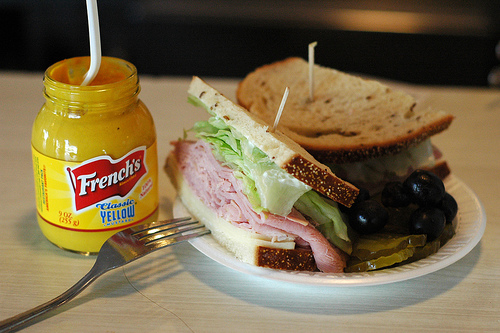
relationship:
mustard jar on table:
[29, 50, 167, 259] [1, 62, 500, 332]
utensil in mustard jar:
[83, 0, 103, 83] [29, 50, 167, 259]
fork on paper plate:
[0, 209, 215, 332] [171, 173, 486, 287]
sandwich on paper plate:
[166, 55, 457, 270] [171, 173, 486, 287]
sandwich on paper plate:
[166, 55, 457, 270] [162, 165, 488, 299]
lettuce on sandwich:
[191, 102, 353, 252] [166, 55, 457, 270]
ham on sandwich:
[168, 131, 344, 274] [166, 55, 457, 270]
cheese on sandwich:
[265, 206, 314, 232] [166, 55, 457, 270]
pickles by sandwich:
[346, 227, 443, 277] [166, 55, 457, 270]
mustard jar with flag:
[29, 50, 167, 259] [66, 145, 147, 212]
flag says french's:
[66, 145, 147, 212] [76, 154, 148, 199]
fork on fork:
[0, 215, 211, 333] [0, 209, 215, 332]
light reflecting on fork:
[138, 219, 180, 255] [0, 209, 215, 332]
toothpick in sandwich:
[306, 38, 322, 108] [166, 55, 457, 270]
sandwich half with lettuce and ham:
[156, 68, 359, 277] [173, 101, 352, 269]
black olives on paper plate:
[344, 166, 461, 243] [171, 173, 486, 287]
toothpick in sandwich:
[308, 42, 319, 101] [166, 55, 457, 270]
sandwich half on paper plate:
[156, 68, 359, 277] [171, 173, 486, 287]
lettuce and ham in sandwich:
[173, 101, 352, 269] [166, 55, 457, 270]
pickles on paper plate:
[346, 227, 443, 277] [171, 173, 486, 287]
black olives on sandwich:
[344, 166, 461, 243] [166, 55, 457, 270]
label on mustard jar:
[26, 142, 167, 233] [29, 50, 167, 259]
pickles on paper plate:
[346, 227, 443, 277] [162, 165, 488, 299]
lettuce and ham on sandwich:
[173, 101, 352, 269] [166, 55, 457, 270]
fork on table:
[0, 209, 215, 332] [1, 62, 500, 332]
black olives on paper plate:
[344, 166, 461, 243] [162, 165, 488, 299]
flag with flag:
[62, 140, 156, 219] [66, 145, 147, 212]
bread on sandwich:
[166, 55, 457, 270] [166, 55, 457, 270]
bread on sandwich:
[236, 55, 451, 158] [166, 55, 457, 270]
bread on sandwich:
[183, 73, 357, 208] [166, 55, 457, 270]